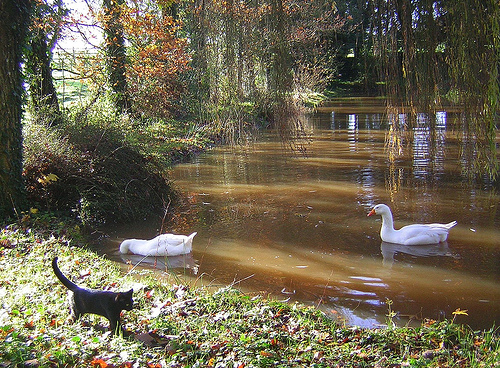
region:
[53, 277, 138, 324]
black cat walking on grass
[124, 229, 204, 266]
white bird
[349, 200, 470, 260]
white bird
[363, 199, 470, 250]
white bird in brown water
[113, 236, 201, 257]
white bird in brown water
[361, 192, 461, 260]
white bird in brown river water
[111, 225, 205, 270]
white bird in brown river water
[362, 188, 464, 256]
white bird in river water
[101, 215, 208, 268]
white bird in river water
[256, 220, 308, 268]
brown water in river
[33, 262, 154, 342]
black cat walking on grass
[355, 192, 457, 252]
white bird in brown river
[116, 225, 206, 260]
white bird in brown river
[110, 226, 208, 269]
white bird in brown water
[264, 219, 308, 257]
brown water in calm river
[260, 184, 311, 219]
brown water in calm river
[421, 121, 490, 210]
brown water in calm river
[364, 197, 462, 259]
swan floating on pond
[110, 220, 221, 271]
swan fishing in pond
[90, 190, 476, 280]
pair of swans in pond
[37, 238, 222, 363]
black cat walking along side of pond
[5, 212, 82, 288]
fallen leaves on grass next to pond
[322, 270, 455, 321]
brown muddy pond water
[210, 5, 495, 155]
tree lmbs hanging down over pond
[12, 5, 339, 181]
trees along side of pond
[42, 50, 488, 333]
pond surrounded by trees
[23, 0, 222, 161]
tree with orange and yellow leaves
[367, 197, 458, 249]
White duck swimming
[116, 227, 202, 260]
White duck with head under water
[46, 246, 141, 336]
Black cat walking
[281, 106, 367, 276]
Brown creek water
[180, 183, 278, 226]
Leaves floating on water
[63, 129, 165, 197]
Growth on creek bank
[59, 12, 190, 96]
Bush with yellow and brown leaves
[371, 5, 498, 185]
Limbs hanging over water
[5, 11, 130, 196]
Trees on creek bank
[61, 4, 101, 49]
Blue skies in background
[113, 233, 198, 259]
a white goose in water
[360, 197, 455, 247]
a white goose in water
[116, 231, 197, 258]
a white goose with head under water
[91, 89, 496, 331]
a small body of muddy water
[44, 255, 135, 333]
a small black cat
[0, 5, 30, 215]
a tall tree trunk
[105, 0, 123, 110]
a tall tree trunk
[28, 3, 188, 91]
a branch with brown leaves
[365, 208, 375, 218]
an orange duck beak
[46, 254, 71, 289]
a cat's uplifted tail